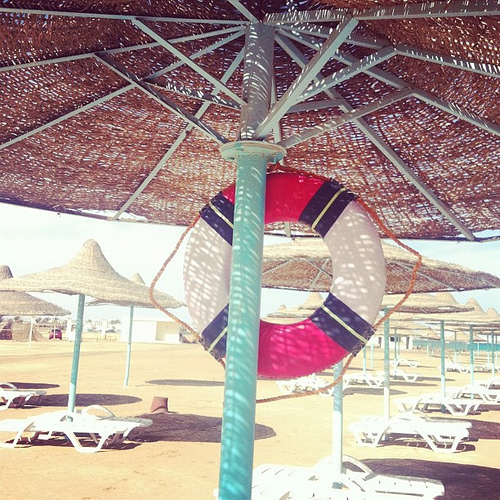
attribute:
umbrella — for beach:
[260, 237, 499, 477]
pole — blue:
[331, 357, 346, 474]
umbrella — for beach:
[84, 273, 185, 309]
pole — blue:
[123, 305, 134, 385]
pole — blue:
[214, 137, 275, 471]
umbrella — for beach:
[391, 292, 473, 379]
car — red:
[48, 327, 63, 341]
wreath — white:
[180, 169, 390, 384]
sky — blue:
[34, 210, 106, 257]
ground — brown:
[150, 446, 197, 489]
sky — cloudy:
[393, 233, 500, 318]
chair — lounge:
[2, 409, 152, 451]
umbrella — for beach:
[484, 307, 499, 324]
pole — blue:
[382, 310, 389, 430]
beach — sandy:
[0, 331, 497, 499]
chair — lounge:
[346, 406, 466, 457]